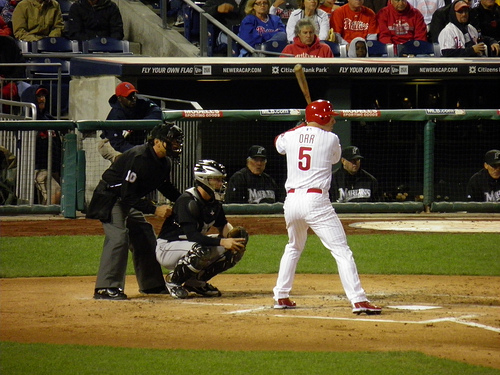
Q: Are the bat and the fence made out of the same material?
A: No, the bat is made of wood and the fence is made of metal.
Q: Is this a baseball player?
A: Yes, this is a baseball player.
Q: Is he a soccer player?
A: No, this is a baseball player.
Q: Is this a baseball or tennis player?
A: This is a baseball player.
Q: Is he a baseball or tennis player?
A: This is a baseball player.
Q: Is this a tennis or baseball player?
A: This is a baseball player.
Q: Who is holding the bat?
A: The player is holding the bat.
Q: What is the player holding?
A: The player is holding the bat.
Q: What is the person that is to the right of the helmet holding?
A: The player is holding the bat.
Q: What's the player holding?
A: The player is holding the bat.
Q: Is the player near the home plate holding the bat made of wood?
A: Yes, the player is holding the bat.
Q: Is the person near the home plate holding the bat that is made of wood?
A: Yes, the player is holding the bat.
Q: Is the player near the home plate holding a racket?
A: No, the player is holding the bat.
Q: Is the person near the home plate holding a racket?
A: No, the player is holding the bat.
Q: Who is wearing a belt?
A: The player is wearing a belt.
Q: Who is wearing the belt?
A: The player is wearing a belt.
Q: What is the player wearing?
A: The player is wearing a belt.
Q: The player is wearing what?
A: The player is wearing a belt.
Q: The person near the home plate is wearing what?
A: The player is wearing a belt.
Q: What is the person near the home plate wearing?
A: The player is wearing a belt.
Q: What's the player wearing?
A: The player is wearing a belt.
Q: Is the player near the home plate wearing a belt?
A: Yes, the player is wearing a belt.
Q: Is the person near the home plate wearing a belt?
A: Yes, the player is wearing a belt.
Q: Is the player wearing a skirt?
A: No, the player is wearing a belt.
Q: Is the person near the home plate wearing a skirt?
A: No, the player is wearing a belt.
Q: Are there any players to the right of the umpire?
A: Yes, there is a player to the right of the umpire.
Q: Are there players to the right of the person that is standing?
A: Yes, there is a player to the right of the umpire.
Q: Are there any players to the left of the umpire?
A: No, the player is to the right of the umpire.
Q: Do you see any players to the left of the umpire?
A: No, the player is to the right of the umpire.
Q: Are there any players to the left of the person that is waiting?
A: No, the player is to the right of the umpire.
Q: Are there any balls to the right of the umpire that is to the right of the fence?
A: No, there is a player to the right of the umpire.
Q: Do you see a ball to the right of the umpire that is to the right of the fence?
A: No, there is a player to the right of the umpire.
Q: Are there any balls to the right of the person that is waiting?
A: No, there is a player to the right of the umpire.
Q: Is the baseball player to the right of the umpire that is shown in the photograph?
A: Yes, the player is to the right of the umpire.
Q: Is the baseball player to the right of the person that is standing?
A: Yes, the player is to the right of the umpire.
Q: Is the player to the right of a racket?
A: No, the player is to the right of the umpire.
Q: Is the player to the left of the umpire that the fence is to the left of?
A: No, the player is to the right of the umpire.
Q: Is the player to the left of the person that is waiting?
A: No, the player is to the right of the umpire.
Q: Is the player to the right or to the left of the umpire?
A: The player is to the right of the umpire.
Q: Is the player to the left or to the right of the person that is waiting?
A: The player is to the right of the umpire.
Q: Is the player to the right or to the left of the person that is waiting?
A: The player is to the right of the umpire.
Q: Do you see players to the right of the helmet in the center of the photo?
A: Yes, there is a player to the right of the helmet.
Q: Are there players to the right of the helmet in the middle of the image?
A: Yes, there is a player to the right of the helmet.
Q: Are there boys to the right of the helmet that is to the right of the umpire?
A: No, there is a player to the right of the helmet.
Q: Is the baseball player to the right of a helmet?
A: Yes, the player is to the right of a helmet.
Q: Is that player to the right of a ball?
A: No, the player is to the right of a helmet.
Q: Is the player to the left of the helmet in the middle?
A: No, the player is to the right of the helmet.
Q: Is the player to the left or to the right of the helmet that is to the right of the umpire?
A: The player is to the right of the helmet.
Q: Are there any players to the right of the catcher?
A: Yes, there is a player to the right of the catcher.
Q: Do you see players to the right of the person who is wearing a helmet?
A: Yes, there is a player to the right of the catcher.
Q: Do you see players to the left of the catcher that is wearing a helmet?
A: No, the player is to the right of the catcher.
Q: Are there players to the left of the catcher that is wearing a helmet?
A: No, the player is to the right of the catcher.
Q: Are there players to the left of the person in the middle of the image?
A: No, the player is to the right of the catcher.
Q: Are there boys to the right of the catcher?
A: No, there is a player to the right of the catcher.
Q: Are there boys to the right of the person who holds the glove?
A: No, there is a player to the right of the catcher.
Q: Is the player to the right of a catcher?
A: Yes, the player is to the right of a catcher.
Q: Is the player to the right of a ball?
A: No, the player is to the right of a catcher.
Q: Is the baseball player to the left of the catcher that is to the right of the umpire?
A: No, the player is to the right of the catcher.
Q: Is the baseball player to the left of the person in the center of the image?
A: No, the player is to the right of the catcher.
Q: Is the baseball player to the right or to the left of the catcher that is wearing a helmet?
A: The player is to the right of the catcher.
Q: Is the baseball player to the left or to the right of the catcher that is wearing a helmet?
A: The player is to the right of the catcher.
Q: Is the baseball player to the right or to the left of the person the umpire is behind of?
A: The player is to the right of the catcher.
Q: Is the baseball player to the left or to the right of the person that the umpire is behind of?
A: The player is to the right of the catcher.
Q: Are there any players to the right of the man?
A: Yes, there is a player to the right of the man.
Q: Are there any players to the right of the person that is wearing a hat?
A: Yes, there is a player to the right of the man.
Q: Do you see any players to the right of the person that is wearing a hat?
A: Yes, there is a player to the right of the man.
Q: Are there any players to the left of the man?
A: No, the player is to the right of the man.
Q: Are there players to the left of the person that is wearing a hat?
A: No, the player is to the right of the man.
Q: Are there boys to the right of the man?
A: No, there is a player to the right of the man.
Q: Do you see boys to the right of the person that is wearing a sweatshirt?
A: No, there is a player to the right of the man.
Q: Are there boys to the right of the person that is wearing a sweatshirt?
A: No, there is a player to the right of the man.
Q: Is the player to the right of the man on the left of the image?
A: Yes, the player is to the right of the man.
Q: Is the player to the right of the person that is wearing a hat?
A: Yes, the player is to the right of the man.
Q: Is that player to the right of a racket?
A: No, the player is to the right of the man.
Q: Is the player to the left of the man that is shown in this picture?
A: No, the player is to the right of the man.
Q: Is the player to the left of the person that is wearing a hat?
A: No, the player is to the right of the man.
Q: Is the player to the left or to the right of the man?
A: The player is to the right of the man.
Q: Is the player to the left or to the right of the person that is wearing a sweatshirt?
A: The player is to the right of the man.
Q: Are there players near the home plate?
A: Yes, there is a player near the home plate.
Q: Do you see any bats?
A: Yes, there is a bat.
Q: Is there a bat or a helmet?
A: Yes, there is a bat.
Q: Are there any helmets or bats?
A: Yes, there is a bat.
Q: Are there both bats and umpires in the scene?
A: Yes, there are both a bat and an umpire.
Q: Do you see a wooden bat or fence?
A: Yes, there is a wood bat.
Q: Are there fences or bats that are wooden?
A: Yes, the bat is wooden.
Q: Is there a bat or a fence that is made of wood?
A: Yes, the bat is made of wood.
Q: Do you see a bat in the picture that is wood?
A: Yes, there is a wood bat.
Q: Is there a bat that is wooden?
A: Yes, there is a bat that is wooden.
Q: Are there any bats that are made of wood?
A: Yes, there is a bat that is made of wood.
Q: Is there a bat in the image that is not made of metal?
A: Yes, there is a bat that is made of wood.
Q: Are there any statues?
A: No, there are no statues.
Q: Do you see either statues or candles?
A: No, there are no statues or candles.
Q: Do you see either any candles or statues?
A: No, there are no statues or candles.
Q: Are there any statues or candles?
A: No, there are no statues or candles.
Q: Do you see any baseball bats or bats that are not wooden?
A: No, there is a bat but it is wooden.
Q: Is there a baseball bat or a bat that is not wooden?
A: No, there is a bat but it is wooden.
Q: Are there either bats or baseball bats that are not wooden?
A: No, there is a bat but it is wooden.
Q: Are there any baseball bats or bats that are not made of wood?
A: No, there is a bat but it is made of wood.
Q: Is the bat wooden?
A: Yes, the bat is wooden.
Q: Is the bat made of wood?
A: Yes, the bat is made of wood.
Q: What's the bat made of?
A: The bat is made of wood.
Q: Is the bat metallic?
A: No, the bat is wooden.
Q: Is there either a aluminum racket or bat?
A: No, there is a bat but it is wooden.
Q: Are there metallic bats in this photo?
A: No, there is a bat but it is wooden.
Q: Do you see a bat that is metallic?
A: No, there is a bat but it is wooden.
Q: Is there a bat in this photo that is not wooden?
A: No, there is a bat but it is wooden.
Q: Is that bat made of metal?
A: No, the bat is made of wood.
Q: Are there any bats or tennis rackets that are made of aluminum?
A: No, there is a bat but it is made of wood.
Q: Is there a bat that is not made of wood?
A: No, there is a bat but it is made of wood.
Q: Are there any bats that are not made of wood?
A: No, there is a bat but it is made of wood.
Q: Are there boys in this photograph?
A: No, there are no boys.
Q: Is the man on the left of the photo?
A: Yes, the man is on the left of the image.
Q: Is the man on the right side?
A: No, the man is on the left of the image.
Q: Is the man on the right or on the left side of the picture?
A: The man is on the left of the image.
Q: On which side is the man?
A: The man is on the left of the image.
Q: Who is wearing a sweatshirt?
A: The man is wearing a sweatshirt.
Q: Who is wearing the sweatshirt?
A: The man is wearing a sweatshirt.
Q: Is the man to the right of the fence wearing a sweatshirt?
A: Yes, the man is wearing a sweatshirt.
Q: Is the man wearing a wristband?
A: No, the man is wearing a sweatshirt.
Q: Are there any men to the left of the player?
A: Yes, there is a man to the left of the player.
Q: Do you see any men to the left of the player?
A: Yes, there is a man to the left of the player.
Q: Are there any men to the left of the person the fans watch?
A: Yes, there is a man to the left of the player.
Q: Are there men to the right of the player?
A: No, the man is to the left of the player.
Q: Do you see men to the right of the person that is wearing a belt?
A: No, the man is to the left of the player.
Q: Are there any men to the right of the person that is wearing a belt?
A: No, the man is to the left of the player.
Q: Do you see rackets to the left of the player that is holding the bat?
A: No, there is a man to the left of the player.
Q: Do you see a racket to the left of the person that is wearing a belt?
A: No, there is a man to the left of the player.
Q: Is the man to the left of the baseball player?
A: Yes, the man is to the left of the player.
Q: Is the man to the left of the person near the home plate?
A: Yes, the man is to the left of the player.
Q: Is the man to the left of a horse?
A: No, the man is to the left of the player.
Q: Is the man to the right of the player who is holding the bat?
A: No, the man is to the left of the player.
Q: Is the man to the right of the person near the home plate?
A: No, the man is to the left of the player.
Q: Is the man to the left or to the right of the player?
A: The man is to the left of the player.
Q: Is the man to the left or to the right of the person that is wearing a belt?
A: The man is to the left of the player.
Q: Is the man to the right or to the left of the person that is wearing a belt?
A: The man is to the left of the player.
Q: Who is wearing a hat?
A: The man is wearing a hat.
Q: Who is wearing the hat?
A: The man is wearing a hat.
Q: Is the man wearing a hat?
A: Yes, the man is wearing a hat.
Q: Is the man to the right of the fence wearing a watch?
A: No, the man is wearing a hat.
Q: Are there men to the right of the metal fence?
A: Yes, there is a man to the right of the fence.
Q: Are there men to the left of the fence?
A: No, the man is to the right of the fence.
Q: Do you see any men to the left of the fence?
A: No, the man is to the right of the fence.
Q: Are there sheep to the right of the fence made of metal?
A: No, there is a man to the right of the fence.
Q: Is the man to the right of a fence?
A: Yes, the man is to the right of a fence.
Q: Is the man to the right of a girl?
A: No, the man is to the right of a fence.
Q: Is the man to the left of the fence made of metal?
A: No, the man is to the right of the fence.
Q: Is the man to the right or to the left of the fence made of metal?
A: The man is to the right of the fence.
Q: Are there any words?
A: Yes, there are words.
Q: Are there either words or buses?
A: Yes, there are words.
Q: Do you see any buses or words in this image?
A: Yes, there are words.